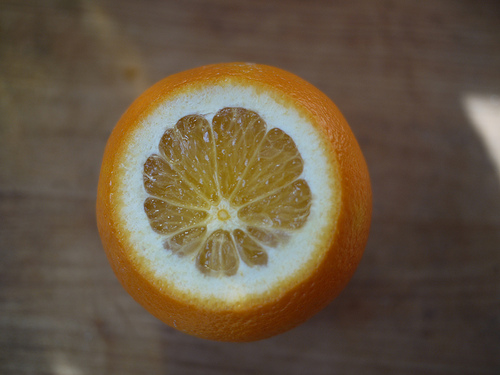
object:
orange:
[87, 58, 377, 345]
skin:
[226, 62, 294, 89]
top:
[105, 72, 345, 317]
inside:
[141, 105, 312, 280]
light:
[182, 131, 248, 185]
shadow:
[305, 276, 336, 312]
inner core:
[205, 198, 244, 235]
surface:
[149, 116, 284, 244]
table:
[0, 0, 500, 375]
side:
[462, 87, 498, 131]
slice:
[238, 175, 315, 232]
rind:
[92, 58, 373, 344]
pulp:
[248, 154, 286, 192]